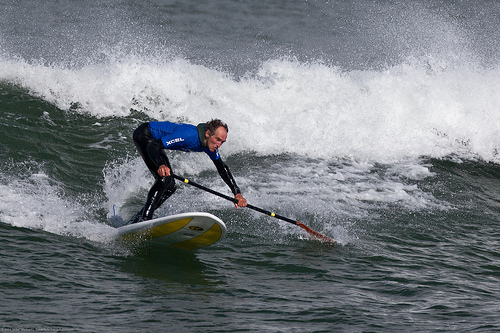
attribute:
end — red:
[283, 205, 343, 259]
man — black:
[124, 100, 230, 177]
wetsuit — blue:
[121, 110, 206, 216]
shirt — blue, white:
[147, 120, 222, 161]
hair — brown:
[199, 119, 229, 134]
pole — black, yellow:
[168, 172, 330, 244]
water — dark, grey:
[368, 202, 493, 327]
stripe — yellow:
[186, 221, 221, 246]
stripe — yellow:
[122, 217, 192, 241]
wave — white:
[5, 58, 495, 172]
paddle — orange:
[297, 207, 356, 257]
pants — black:
[129, 122, 177, 222]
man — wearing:
[114, 104, 285, 239]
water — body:
[1, 2, 498, 328]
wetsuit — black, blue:
[125, 117, 248, 227]